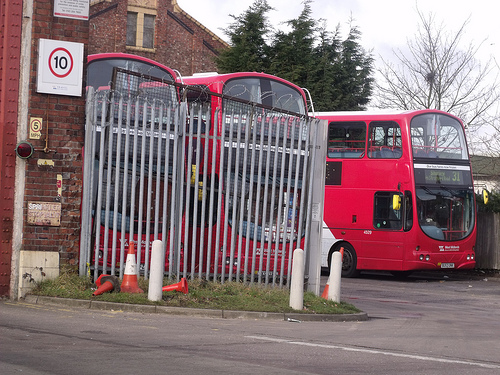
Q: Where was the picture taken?
A: It was taken at the parking lot.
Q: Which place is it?
A: It is a parking lot.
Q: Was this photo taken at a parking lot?
A: Yes, it was taken in a parking lot.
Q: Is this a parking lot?
A: Yes, it is a parking lot.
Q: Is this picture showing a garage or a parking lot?
A: It is showing a parking lot.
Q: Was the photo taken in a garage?
A: No, the picture was taken in a parking lot.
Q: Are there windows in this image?
A: Yes, there are windows.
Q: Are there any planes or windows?
A: Yes, there are windows.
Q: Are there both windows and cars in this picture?
A: No, there are windows but no cars.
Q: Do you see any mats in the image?
A: No, there are no mats.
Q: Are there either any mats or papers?
A: No, there are no mats or papers.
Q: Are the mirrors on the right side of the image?
A: Yes, the mirrors are on the right of the image.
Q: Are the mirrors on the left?
A: No, the mirrors are on the right of the image.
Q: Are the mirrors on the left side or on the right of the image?
A: The mirrors are on the right of the image.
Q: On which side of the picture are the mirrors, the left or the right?
A: The mirrors are on the right of the image.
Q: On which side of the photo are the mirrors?
A: The mirrors are on the right of the image.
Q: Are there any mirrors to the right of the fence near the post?
A: Yes, there are mirrors to the right of the fence.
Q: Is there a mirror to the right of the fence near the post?
A: Yes, there are mirrors to the right of the fence.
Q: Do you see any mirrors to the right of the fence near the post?
A: Yes, there are mirrors to the right of the fence.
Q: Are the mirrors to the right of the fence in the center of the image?
A: Yes, the mirrors are to the right of the fence.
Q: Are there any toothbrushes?
A: No, there are no toothbrushes.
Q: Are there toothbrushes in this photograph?
A: No, there are no toothbrushes.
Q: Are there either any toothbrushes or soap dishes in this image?
A: No, there are no toothbrushes or soap dishes.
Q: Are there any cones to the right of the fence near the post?
A: Yes, there is a cone to the right of the fence.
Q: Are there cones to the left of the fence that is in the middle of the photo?
A: No, the cone is to the right of the fence.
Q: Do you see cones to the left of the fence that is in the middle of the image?
A: No, the cone is to the right of the fence.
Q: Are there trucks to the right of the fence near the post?
A: No, there is a cone to the right of the fence.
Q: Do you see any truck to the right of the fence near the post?
A: No, there is a cone to the right of the fence.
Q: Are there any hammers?
A: No, there are no hammers.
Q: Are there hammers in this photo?
A: No, there are no hammers.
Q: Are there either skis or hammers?
A: No, there are no hammers or skis.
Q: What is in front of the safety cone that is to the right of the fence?
A: The pole is in front of the traffic cone.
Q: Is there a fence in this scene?
A: Yes, there is a fence.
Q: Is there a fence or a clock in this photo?
A: Yes, there is a fence.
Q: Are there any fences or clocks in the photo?
A: Yes, there is a fence.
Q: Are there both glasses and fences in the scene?
A: No, there is a fence but no glasses.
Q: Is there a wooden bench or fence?
A: Yes, there is a wood fence.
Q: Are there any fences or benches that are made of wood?
A: Yes, the fence is made of wood.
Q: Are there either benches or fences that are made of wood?
A: Yes, the fence is made of wood.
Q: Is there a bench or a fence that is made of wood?
A: Yes, the fence is made of wood.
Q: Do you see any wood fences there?
A: Yes, there is a wood fence.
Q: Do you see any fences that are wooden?
A: Yes, there is a fence that is wooden.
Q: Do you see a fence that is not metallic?
A: Yes, there is a wooden fence.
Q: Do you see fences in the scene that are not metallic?
A: Yes, there is a wooden fence.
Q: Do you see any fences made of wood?
A: Yes, there is a fence that is made of wood.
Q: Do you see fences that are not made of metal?
A: Yes, there is a fence that is made of wood.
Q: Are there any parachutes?
A: No, there are no parachutes.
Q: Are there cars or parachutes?
A: No, there are no parachutes or cars.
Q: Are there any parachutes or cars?
A: No, there are no parachutes or cars.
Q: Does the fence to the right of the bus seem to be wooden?
A: Yes, the fence is wooden.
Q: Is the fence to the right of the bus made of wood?
A: Yes, the fence is made of wood.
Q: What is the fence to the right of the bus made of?
A: The fence is made of wood.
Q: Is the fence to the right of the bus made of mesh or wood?
A: The fence is made of wood.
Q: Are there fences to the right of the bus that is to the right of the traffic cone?
A: Yes, there is a fence to the right of the bus.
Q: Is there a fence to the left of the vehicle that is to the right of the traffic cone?
A: No, the fence is to the right of the bus.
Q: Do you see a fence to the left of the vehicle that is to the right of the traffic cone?
A: No, the fence is to the right of the bus.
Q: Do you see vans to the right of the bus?
A: No, there is a fence to the right of the bus.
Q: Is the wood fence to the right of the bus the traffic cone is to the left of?
A: Yes, the fence is to the right of the bus.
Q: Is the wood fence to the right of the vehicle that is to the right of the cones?
A: Yes, the fence is to the right of the bus.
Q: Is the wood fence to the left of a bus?
A: No, the fence is to the right of a bus.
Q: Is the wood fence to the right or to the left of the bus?
A: The fence is to the right of the bus.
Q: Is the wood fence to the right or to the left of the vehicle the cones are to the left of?
A: The fence is to the right of the bus.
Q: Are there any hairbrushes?
A: No, there are no hairbrushes.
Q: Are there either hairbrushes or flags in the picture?
A: No, there are no hairbrushes or flags.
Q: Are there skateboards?
A: No, there are no skateboards.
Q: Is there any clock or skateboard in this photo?
A: No, there are no skateboards or clocks.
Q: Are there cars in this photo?
A: No, there are no cars.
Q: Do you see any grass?
A: Yes, there is grass.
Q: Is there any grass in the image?
A: Yes, there is grass.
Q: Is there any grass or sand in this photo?
A: Yes, there is grass.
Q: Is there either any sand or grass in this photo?
A: Yes, there is grass.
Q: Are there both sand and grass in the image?
A: No, there is grass but no sand.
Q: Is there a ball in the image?
A: No, there are no balls.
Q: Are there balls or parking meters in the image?
A: No, there are no balls or parking meters.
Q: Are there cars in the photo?
A: No, there are no cars.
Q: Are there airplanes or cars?
A: No, there are no cars or airplanes.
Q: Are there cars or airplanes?
A: No, there are no cars or airplanes.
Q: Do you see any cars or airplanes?
A: No, there are no cars or airplanes.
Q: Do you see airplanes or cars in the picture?
A: No, there are no cars or airplanes.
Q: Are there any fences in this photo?
A: Yes, there is a fence.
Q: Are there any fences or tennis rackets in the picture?
A: Yes, there is a fence.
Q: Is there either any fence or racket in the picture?
A: Yes, there is a fence.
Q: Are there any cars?
A: No, there are no cars.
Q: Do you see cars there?
A: No, there are no cars.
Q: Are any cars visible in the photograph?
A: No, there are no cars.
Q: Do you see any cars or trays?
A: No, there are no cars or trays.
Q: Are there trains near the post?
A: No, there is a fence near the post.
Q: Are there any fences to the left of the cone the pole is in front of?
A: Yes, there is a fence to the left of the cone.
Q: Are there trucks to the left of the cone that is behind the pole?
A: No, there is a fence to the left of the cone.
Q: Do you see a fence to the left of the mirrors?
A: Yes, there is a fence to the left of the mirrors.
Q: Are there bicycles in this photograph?
A: No, there are no bicycles.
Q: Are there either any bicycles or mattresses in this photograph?
A: No, there are no bicycles or mattresses.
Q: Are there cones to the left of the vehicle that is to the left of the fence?
A: Yes, there is a cone to the left of the bus.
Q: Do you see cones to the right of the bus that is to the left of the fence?
A: No, the cone is to the left of the bus.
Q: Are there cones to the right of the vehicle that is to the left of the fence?
A: No, the cone is to the left of the bus.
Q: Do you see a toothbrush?
A: No, there are no toothbrushes.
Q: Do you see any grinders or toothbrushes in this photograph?
A: No, there are no toothbrushes or grinders.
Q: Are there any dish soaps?
A: No, there are no dish soaps.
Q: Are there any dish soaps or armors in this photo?
A: No, there are no dish soaps or armors.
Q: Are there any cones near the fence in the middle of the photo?
A: Yes, there are cones near the fence.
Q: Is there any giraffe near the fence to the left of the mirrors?
A: No, there are cones near the fence.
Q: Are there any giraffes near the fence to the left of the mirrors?
A: No, there are cones near the fence.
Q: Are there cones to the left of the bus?
A: Yes, there are cones to the left of the bus.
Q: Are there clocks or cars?
A: No, there are no cars or clocks.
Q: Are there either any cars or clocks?
A: No, there are no cars or clocks.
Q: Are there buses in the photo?
A: Yes, there is a bus.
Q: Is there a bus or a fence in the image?
A: Yes, there is a bus.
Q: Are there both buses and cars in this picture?
A: No, there is a bus but no cars.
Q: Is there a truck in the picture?
A: No, there are no trucks.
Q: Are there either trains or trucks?
A: No, there are no trucks or trains.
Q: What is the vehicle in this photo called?
A: The vehicle is a bus.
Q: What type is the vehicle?
A: The vehicle is a bus.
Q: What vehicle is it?
A: The vehicle is a bus.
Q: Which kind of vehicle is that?
A: This is a bus.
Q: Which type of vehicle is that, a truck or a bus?
A: This is a bus.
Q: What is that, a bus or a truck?
A: That is a bus.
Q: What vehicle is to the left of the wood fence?
A: The vehicle is a bus.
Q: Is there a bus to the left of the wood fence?
A: Yes, there is a bus to the left of the fence.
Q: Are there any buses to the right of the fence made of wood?
A: No, the bus is to the left of the fence.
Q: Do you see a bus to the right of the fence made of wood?
A: No, the bus is to the left of the fence.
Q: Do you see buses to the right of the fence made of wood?
A: No, the bus is to the left of the fence.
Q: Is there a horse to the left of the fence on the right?
A: No, there is a bus to the left of the fence.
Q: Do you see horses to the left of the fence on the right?
A: No, there is a bus to the left of the fence.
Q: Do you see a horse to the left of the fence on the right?
A: No, there is a bus to the left of the fence.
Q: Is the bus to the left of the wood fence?
A: Yes, the bus is to the left of the fence.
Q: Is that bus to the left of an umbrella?
A: No, the bus is to the left of the fence.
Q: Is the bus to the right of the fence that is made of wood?
A: No, the bus is to the left of the fence.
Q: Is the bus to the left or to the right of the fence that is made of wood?
A: The bus is to the left of the fence.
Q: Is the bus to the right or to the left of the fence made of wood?
A: The bus is to the left of the fence.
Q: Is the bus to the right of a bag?
A: No, the bus is to the right of the safety cone.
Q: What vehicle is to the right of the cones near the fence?
A: The vehicle is a bus.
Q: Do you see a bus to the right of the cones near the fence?
A: Yes, there is a bus to the right of the cones.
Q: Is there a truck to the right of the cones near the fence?
A: No, there is a bus to the right of the cones.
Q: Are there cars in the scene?
A: No, there are no cars.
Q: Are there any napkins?
A: No, there are no napkins.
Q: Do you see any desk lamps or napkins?
A: No, there are no napkins or desk lamps.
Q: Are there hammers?
A: No, there are no hammers.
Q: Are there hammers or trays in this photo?
A: No, there are no hammers or trays.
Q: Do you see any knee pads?
A: No, there are no knee pads.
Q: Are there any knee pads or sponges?
A: No, there are no knee pads or sponges.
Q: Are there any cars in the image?
A: No, there are no cars.